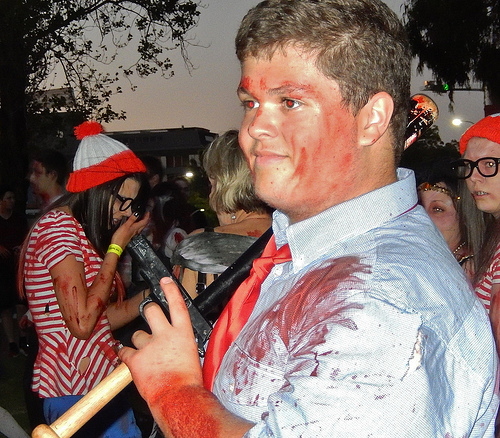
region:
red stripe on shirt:
[35, 364, 66, 397]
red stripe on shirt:
[38, 372, 61, 397]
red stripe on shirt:
[38, 381, 53, 398]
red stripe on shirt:
[35, 320, 62, 332]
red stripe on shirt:
[32, 314, 61, 326]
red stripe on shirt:
[27, 290, 57, 303]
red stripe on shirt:
[23, 273, 53, 291]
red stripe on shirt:
[475, 290, 490, 303]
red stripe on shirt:
[480, 273, 491, 287]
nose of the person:
[231, 95, 284, 143]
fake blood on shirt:
[244, 253, 354, 345]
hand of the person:
[71, 275, 204, 413]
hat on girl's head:
[52, 127, 140, 192]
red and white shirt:
[17, 220, 118, 367]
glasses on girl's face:
[104, 178, 149, 222]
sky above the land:
[156, 50, 231, 117]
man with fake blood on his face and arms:
[145, 5, 457, 420]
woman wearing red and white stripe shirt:
[27, 102, 192, 423]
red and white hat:
[49, 110, 146, 186]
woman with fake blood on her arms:
[19, 110, 176, 385]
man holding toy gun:
[120, 11, 438, 423]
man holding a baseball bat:
[139, 16, 466, 403]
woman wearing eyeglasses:
[35, 104, 176, 390]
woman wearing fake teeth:
[451, 109, 498, 264]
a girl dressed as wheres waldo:
[20, 111, 170, 421]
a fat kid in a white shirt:
[224, 3, 482, 437]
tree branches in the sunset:
[32, 0, 210, 107]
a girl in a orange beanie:
[455, 104, 497, 248]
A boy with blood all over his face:
[147, 40, 404, 250]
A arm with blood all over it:
[34, 310, 262, 432]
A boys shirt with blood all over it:
[103, 190, 451, 432]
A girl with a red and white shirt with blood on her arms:
[0, 134, 142, 381]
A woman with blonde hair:
[162, 124, 277, 294]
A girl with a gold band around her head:
[404, 171, 472, 275]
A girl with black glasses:
[93, 170, 154, 220]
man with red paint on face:
[236, 1, 410, 208]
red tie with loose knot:
[201, 238, 288, 385]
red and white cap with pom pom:
[66, 121, 144, 191]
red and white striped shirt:
[24, 211, 126, 397]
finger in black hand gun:
[135, 239, 214, 351]